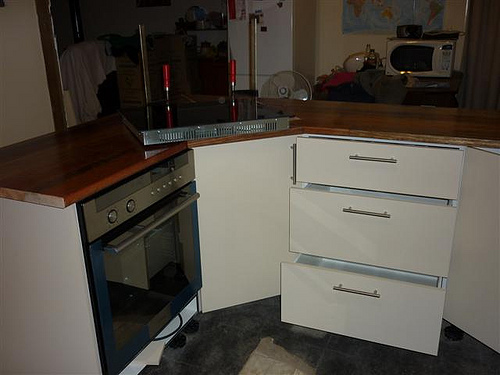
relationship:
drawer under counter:
[297, 139, 458, 196] [0, 88, 500, 210]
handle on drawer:
[343, 203, 394, 219] [297, 139, 458, 196]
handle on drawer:
[335, 286, 384, 302] [287, 268, 435, 352]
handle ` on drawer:
[348, 153, 399, 166] [297, 139, 458, 196]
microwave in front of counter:
[385, 31, 455, 78] [0, 88, 500, 210]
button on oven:
[128, 197, 138, 212] [82, 150, 203, 373]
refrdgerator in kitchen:
[225, 0, 312, 90] [18, 4, 491, 370]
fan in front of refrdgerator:
[262, 66, 313, 102] [225, 0, 312, 90]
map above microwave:
[344, 2, 448, 34] [385, 31, 455, 78]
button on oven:
[104, 207, 120, 225] [82, 150, 203, 373]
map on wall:
[344, 2, 448, 34] [312, 5, 468, 77]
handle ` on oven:
[113, 189, 225, 247] [82, 150, 203, 373]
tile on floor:
[211, 329, 244, 358] [211, 332, 485, 372]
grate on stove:
[151, 118, 287, 138] [127, 95, 309, 128]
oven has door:
[82, 150, 203, 373] [104, 229, 198, 333]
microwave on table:
[385, 31, 455, 78] [334, 79, 452, 104]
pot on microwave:
[397, 23, 427, 39] [385, 31, 455, 78]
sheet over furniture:
[61, 49, 106, 104] [98, 82, 122, 110]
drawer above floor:
[297, 139, 458, 196] [211, 332, 485, 372]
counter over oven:
[7, 118, 153, 197] [82, 150, 203, 373]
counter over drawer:
[0, 88, 500, 210] [297, 139, 458, 196]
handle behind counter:
[225, 60, 238, 93] [0, 88, 500, 210]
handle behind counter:
[159, 69, 174, 98] [0, 88, 500, 210]